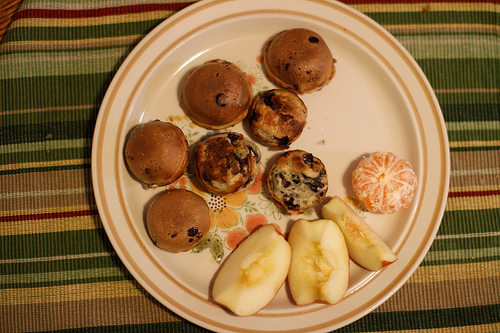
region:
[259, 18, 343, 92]
round piece of food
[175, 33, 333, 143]
three pieces of food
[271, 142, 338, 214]
brown and white piece of food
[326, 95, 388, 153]
plate under the food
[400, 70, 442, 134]
lines on the plate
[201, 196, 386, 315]
white pieces of food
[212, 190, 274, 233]
design under the food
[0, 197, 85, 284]
table under the plate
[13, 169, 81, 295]
colorful tablecloth under the plate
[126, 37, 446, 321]
many pieces of food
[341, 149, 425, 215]
Naval orange on the plate.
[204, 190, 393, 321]
Apples cut up on the plate.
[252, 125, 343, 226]
Blueberry muffin on the plate.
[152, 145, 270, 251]
Fruit design on the plate.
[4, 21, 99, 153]
Striped place under the plate.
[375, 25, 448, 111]
Orange rings around the plate.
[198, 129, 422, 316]
This snack was prepared for a child.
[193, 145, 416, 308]
This healthy snack was prepared at home.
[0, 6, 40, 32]
Bit of brown table.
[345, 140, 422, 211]
Small peeled naval orange.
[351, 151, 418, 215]
A small orange on the right side of the plate.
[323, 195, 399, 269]
Apple slice next to the orange.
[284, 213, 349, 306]
Middle slice of apple.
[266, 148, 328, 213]
Small round muffin next to the apples and orange.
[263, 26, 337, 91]
The top most brown muffin.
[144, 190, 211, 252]
Bottom most brown muffin.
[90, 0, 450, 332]
A white and orange plate with flowers on it.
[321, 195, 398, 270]
A thinner apple slice.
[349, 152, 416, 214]
A small clemintine orange on a plate.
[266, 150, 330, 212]
Muffin with the most dark spots on it next to the apples.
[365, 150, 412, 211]
The peeled orange on the plate.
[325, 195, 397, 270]
The slice of apple on the plate.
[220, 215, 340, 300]
The chunks of apple on the plate.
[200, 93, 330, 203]
The burnt muffins on the plate.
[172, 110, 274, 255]
The flower design on the plate.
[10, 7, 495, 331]
The striped design table cloth.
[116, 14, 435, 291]
The lines on the plate.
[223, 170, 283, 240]
The orange flowers on the plate design.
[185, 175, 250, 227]
The yellow flower on the plate design.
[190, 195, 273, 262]
The green leaves on the plate design.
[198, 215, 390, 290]
Three apples are sliced.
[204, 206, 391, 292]
The apples are on the plate.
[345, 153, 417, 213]
The orange is peeled.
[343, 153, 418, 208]
The orange is on the plate.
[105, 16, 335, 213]
The muffins are on the plate.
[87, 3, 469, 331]
The plate is white.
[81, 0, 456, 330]
The edge is tan.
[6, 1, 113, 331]
The table cloth is green.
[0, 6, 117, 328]
The table cloth is striped.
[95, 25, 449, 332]
The food is on the plate.